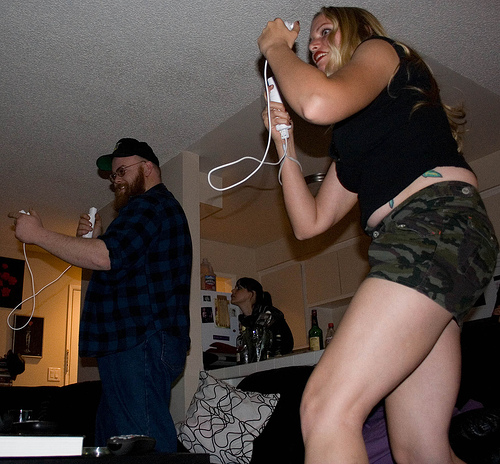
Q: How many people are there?
A: 3.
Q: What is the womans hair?
A: Blonde.